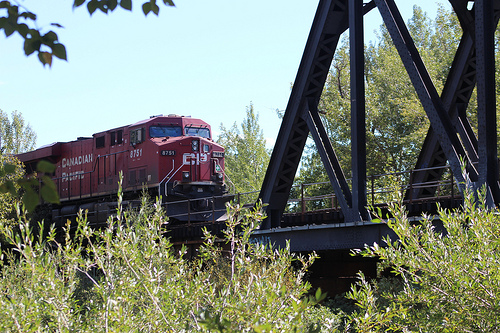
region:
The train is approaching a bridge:
[20, 10, 497, 315]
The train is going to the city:
[5, 70, 475, 315]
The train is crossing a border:
[0, 33, 495, 319]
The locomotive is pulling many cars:
[13, 70, 498, 322]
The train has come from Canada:
[13, 90, 489, 325]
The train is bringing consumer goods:
[0, 55, 497, 301]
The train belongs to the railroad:
[0, 60, 490, 306]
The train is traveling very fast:
[15, 46, 493, 306]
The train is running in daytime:
[0, 76, 497, 296]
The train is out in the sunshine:
[8, 73, 492, 320]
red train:
[31, 108, 229, 217]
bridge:
[267, 7, 496, 214]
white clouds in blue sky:
[80, 51, 138, 92]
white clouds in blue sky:
[176, 19, 222, 48]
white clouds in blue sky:
[215, 6, 261, 51]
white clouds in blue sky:
[175, 42, 224, 75]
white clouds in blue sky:
[85, 48, 122, 79]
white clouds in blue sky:
[27, 93, 67, 120]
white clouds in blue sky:
[102, 26, 147, 72]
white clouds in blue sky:
[158, 51, 191, 82]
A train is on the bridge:
[13, 87, 373, 258]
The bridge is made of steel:
[242, 8, 498, 258]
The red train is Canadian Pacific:
[12, 104, 239, 231]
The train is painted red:
[22, 80, 230, 251]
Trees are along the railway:
[30, 212, 499, 312]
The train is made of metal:
[8, 106, 230, 249]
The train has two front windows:
[143, 116, 211, 143]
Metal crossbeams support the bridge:
[260, 8, 496, 239]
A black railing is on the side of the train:
[27, 154, 129, 200]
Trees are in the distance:
[324, 26, 464, 186]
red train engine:
[23, 120, 249, 229]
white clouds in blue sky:
[3, 71, 30, 100]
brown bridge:
[246, 3, 493, 219]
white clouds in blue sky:
[35, 85, 69, 113]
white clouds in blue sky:
[88, 35, 124, 65]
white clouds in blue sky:
[104, 81, 146, 109]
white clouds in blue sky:
[138, 56, 178, 81]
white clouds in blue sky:
[186, 42, 251, 80]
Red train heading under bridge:
[3, 113, 228, 204]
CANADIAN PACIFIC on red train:
[55, 150, 99, 184]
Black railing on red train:
[40, 148, 130, 207]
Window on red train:
[147, 124, 182, 139]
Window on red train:
[183, 125, 210, 140]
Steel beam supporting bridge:
[301, 105, 352, 216]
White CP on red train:
[182, 148, 207, 168]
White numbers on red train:
[128, 147, 144, 159]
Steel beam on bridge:
[250, 0, 347, 227]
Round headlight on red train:
[182, 170, 189, 180]